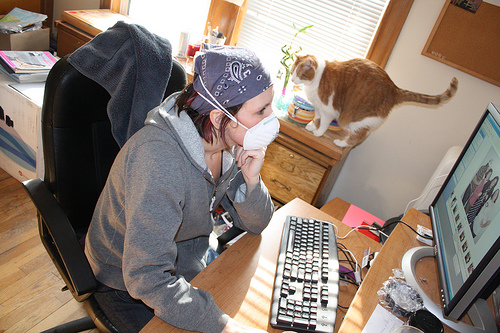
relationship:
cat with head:
[285, 43, 462, 152] [285, 50, 320, 92]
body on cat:
[317, 60, 395, 125] [288, 50, 460, 147]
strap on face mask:
[191, 74, 245, 130] [195, 75, 280, 152]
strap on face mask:
[195, 92, 245, 131] [195, 75, 280, 152]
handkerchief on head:
[183, 39, 282, 114] [173, 43, 285, 158]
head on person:
[173, 43, 285, 158] [82, 41, 281, 333]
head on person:
[177, 44, 281, 148] [135, 57, 278, 326]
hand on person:
[229, 142, 276, 233] [82, 40, 280, 331]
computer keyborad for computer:
[267, 214, 339, 331] [257, 109, 493, 324]